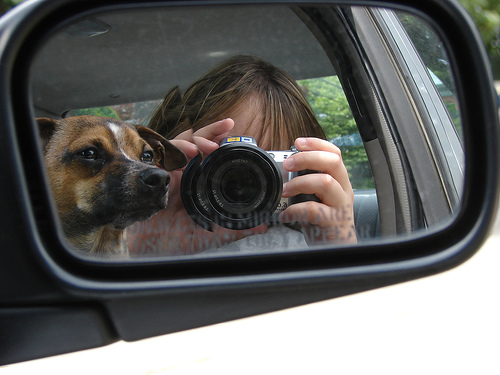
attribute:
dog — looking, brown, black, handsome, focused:
[34, 115, 188, 258]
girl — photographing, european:
[140, 52, 359, 259]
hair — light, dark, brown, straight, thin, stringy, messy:
[146, 58, 327, 150]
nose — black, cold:
[140, 166, 171, 188]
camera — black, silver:
[180, 136, 322, 233]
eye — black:
[141, 149, 154, 162]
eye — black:
[78, 148, 101, 160]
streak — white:
[105, 121, 136, 162]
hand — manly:
[157, 117, 268, 256]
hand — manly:
[278, 136, 357, 247]